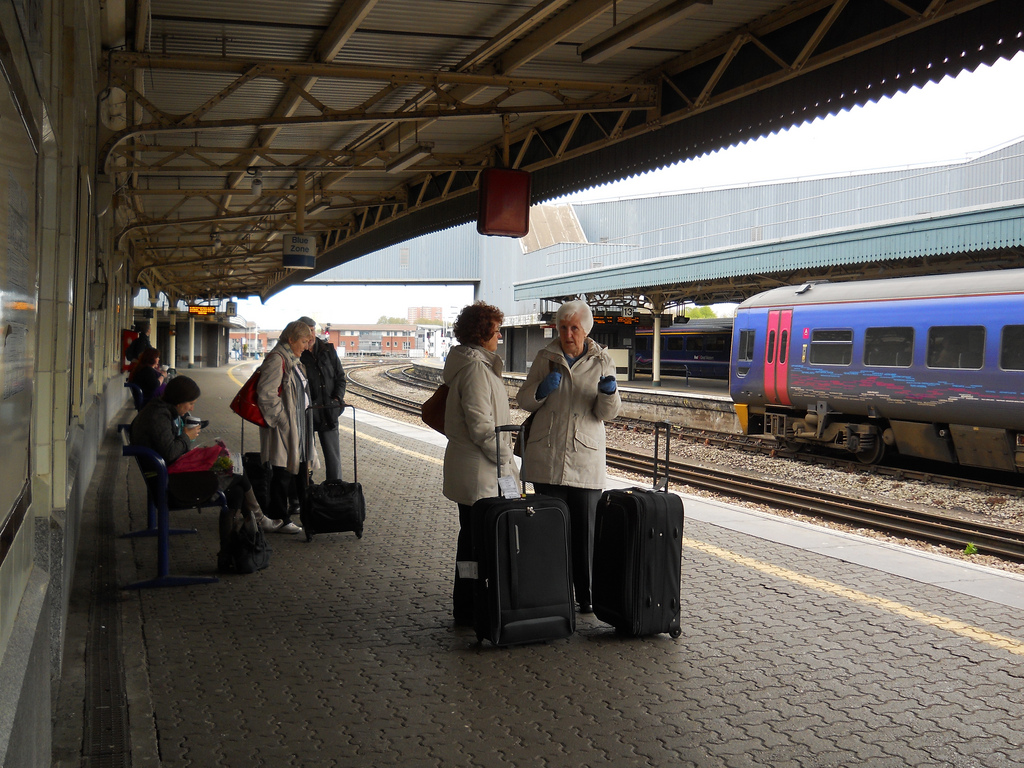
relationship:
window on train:
[733, 323, 759, 365] [722, 284, 1023, 494]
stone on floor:
[659, 707, 707, 745] [611, 665, 808, 765]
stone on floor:
[621, 699, 656, 732] [535, 691, 736, 765]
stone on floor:
[589, 725, 634, 757] [550, 685, 680, 765]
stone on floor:
[532, 702, 562, 742] [404, 640, 739, 764]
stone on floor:
[558, 693, 597, 728] [395, 659, 724, 765]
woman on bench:
[128, 375, 269, 568] [128, 375, 269, 568]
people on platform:
[258, 311, 376, 528] [103, 408, 428, 601]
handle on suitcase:
[484, 421, 523, 495] [444, 484, 596, 642]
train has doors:
[766, 310, 779, 388] [759, 301, 778, 393]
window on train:
[807, 327, 856, 360] [807, 343, 856, 360]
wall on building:
[84, 304, 101, 359] [84, 304, 101, 359]